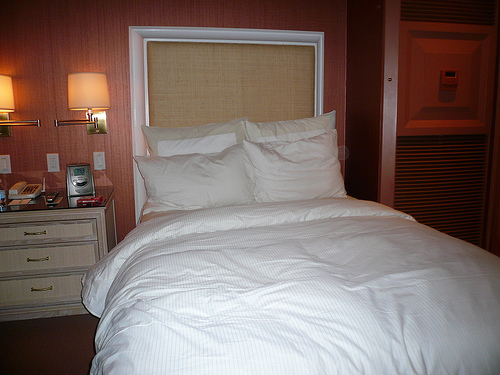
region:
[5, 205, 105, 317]
a white dresser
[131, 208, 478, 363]
a white blanket on the bed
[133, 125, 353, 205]
pillows on the bed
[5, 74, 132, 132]
lamps on the wall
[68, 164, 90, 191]
an alarm clock on the table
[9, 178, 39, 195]
a white telephone on the table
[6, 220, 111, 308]
the drawers of the desk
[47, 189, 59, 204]
a remote on the table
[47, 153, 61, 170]
an electrical socket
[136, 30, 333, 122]
the headboard of the bed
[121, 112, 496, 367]
the bed is made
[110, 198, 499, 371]
blanket on the bed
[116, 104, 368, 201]
pillows on the bed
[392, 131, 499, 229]
the vent beside the bed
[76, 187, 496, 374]
the blanket is white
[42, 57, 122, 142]
the light on the wall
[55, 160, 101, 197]
clock on the nightstand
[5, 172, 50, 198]
telephone on the nightstand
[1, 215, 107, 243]
drawer of the nightstand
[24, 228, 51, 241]
handle of the drawer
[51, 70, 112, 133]
the bedside lamp is on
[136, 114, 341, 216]
the pillow cases are white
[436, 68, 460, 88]
a temperature control panel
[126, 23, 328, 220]
the window is white framed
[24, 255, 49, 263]
metal drawer pulls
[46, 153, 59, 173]
electrical outlet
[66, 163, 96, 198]
the radio is silver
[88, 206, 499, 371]
white down comforter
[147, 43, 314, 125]
beige window dressing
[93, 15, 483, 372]
a large bed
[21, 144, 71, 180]
a white power outlet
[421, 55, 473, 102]
her is a thermostat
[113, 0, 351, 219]
a large headboard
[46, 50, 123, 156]
the lamp can extend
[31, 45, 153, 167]
the lamp folds in and out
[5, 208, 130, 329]
here are some drawers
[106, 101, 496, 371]
the bedding is white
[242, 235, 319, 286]
the bed is made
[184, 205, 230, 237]
the blanket is folded down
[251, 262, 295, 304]
the blanket is white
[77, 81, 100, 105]
the light is on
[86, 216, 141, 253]
the dresser is by the bed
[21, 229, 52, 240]
the handle is gold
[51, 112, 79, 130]
the light is hooked to the wall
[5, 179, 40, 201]
a white corded telephone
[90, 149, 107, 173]
a white light switch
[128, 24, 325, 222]
a window with a white colored trim and shade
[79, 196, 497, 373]
a white wrinkled comforter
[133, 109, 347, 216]
four white colored pillows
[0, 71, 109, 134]
two lamps attached to the wall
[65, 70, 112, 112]
an illuminated lamp shade